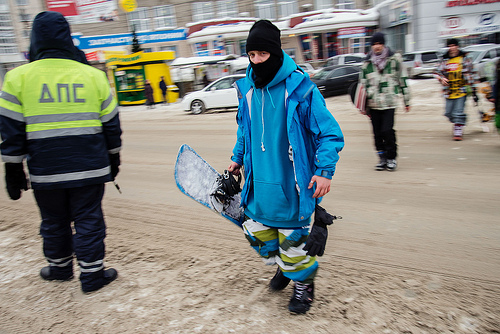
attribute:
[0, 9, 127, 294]
person — dressed for cold weather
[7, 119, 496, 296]
road — snowy, brown and white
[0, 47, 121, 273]
clothes — black, silver and yellow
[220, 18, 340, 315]
winter clothes — dark